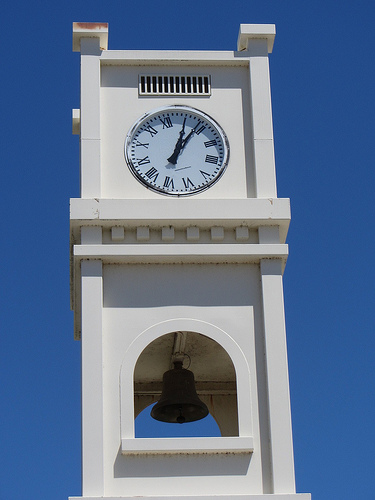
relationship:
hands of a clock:
[169, 108, 182, 163] [115, 106, 254, 200]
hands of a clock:
[168, 114, 188, 164] [115, 106, 254, 200]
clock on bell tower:
[123, 101, 232, 197] [68, 21, 311, 499]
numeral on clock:
[136, 155, 150, 164] [109, 109, 210, 179]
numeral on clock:
[202, 134, 223, 151] [123, 101, 232, 197]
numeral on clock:
[136, 155, 150, 164] [123, 101, 232, 197]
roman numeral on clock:
[159, 114, 174, 129] [123, 101, 232, 197]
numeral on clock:
[132, 142, 153, 148] [126, 88, 238, 188]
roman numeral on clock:
[146, 167, 158, 182] [123, 101, 232, 197]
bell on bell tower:
[144, 355, 228, 442] [68, 21, 311, 499]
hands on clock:
[168, 114, 188, 164] [123, 101, 232, 197]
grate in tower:
[138, 72, 212, 95] [70, 20, 311, 497]